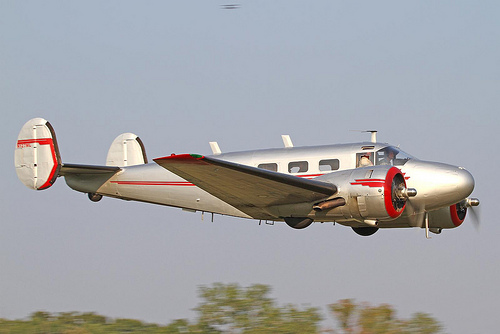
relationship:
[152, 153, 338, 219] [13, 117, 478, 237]
wing on airplaine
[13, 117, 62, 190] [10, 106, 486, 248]
tail of plane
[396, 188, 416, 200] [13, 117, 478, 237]
propellor of airplaine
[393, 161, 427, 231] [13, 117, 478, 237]
propellor of airplaine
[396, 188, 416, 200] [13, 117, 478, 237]
propellor on side of airplaine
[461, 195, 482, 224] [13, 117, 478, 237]
engine propeller on side of airplaine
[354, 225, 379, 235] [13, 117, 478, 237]
wheel on airplaine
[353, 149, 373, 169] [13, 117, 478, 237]
window on airplaine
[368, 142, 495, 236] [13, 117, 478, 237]
nose on airplaine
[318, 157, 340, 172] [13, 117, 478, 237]
window in front of airplaine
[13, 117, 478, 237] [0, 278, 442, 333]
airplaine moving past trees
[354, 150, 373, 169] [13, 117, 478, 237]
man flying airplaine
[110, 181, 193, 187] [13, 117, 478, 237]
red stripe on airplaine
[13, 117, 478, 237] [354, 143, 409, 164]
airplaine has window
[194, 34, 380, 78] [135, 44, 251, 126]
sky has clouds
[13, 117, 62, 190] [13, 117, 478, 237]
tail on airplaine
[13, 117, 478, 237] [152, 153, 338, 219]
airplaine has wing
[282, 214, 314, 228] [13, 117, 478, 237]
wheel on airplaine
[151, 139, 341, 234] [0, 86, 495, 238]
wing on plane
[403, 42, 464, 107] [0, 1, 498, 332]
white clouds in blue sky